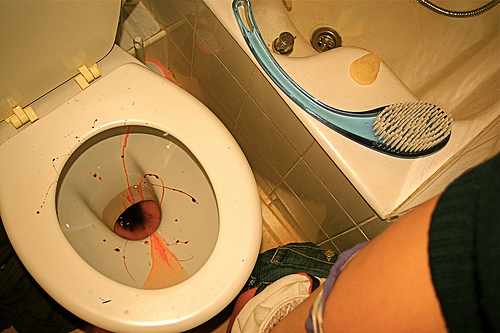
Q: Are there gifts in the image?
A: No, there are no gifts.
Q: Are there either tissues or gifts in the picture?
A: No, there are no gifts or tissues.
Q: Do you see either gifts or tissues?
A: No, there are no gifts or tissues.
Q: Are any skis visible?
A: No, there are no skis.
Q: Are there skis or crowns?
A: No, there are no skis or crowns.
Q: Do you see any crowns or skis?
A: No, there are no skis or crowns.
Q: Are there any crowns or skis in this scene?
A: No, there are no skis or crowns.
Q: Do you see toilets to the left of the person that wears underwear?
A: Yes, there is a toilet to the left of the person.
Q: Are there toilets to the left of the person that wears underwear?
A: Yes, there is a toilet to the left of the person.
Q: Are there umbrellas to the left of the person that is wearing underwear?
A: No, there is a toilet to the left of the person.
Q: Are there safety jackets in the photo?
A: No, there are no safety jackets.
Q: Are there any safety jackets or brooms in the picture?
A: No, there are no safety jackets or brooms.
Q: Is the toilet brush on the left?
A: Yes, the toilet brush is on the left of the image.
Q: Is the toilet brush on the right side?
A: No, the toilet brush is on the left of the image.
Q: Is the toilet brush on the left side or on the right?
A: The toilet brush is on the left of the image.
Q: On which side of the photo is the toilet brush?
A: The toilet brush is on the left of the image.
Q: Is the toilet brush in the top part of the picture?
A: Yes, the toilet brush is in the top of the image.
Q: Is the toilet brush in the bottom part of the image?
A: No, the toilet brush is in the top of the image.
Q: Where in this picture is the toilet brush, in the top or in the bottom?
A: The toilet brush is in the top of the image.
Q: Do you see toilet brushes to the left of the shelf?
A: Yes, there is a toilet brush to the left of the shelf.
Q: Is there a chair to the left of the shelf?
A: No, there is a toilet brush to the left of the shelf.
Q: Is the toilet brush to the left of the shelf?
A: Yes, the toilet brush is to the left of the shelf.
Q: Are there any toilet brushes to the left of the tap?
A: Yes, there is a toilet brush to the left of the tap.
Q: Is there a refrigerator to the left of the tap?
A: No, there is a toilet brush to the left of the tap.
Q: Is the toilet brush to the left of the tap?
A: Yes, the toilet brush is to the left of the tap.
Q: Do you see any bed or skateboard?
A: No, there are no skateboards or beds.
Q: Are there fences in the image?
A: No, there are no fences.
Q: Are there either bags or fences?
A: No, there are no fences or bags.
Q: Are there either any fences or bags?
A: No, there are no fences or bags.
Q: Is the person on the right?
A: Yes, the person is on the right of the image.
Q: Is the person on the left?
A: No, the person is on the right of the image.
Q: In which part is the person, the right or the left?
A: The person is on the right of the image.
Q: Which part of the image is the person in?
A: The person is on the right of the image.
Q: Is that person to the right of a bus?
A: No, the person is to the right of a toilet.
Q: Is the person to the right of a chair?
A: No, the person is to the right of a toilet.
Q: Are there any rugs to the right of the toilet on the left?
A: No, there is a person to the right of the toilet.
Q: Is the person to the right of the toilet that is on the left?
A: Yes, the person is to the right of the toilet.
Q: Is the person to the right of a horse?
A: No, the person is to the right of the toilet.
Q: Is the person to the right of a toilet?
A: Yes, the person is to the right of a toilet.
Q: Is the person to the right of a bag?
A: No, the person is to the right of a toilet.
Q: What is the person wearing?
A: The person is wearing underwear.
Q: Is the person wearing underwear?
A: Yes, the person is wearing underwear.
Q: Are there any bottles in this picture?
A: No, there are no bottles.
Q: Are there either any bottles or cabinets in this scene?
A: No, there are no bottles or cabinets.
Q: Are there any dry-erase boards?
A: No, there are no dry-erase boards.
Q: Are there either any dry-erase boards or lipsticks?
A: No, there are no dry-erase boards or lipsticks.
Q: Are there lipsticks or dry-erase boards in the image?
A: No, there are no dry-erase boards or lipsticks.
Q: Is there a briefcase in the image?
A: No, there are no briefcases.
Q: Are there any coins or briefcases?
A: No, there are no briefcases or coins.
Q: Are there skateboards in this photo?
A: No, there are no skateboards.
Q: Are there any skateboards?
A: No, there are no skateboards.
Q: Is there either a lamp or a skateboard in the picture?
A: No, there are no skateboards or lamps.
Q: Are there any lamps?
A: No, there are no lamps.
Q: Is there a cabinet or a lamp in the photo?
A: No, there are no lamps or cabinets.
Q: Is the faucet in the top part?
A: Yes, the faucet is in the top of the image.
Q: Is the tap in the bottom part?
A: No, the tap is in the top of the image.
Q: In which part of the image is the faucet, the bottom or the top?
A: The faucet is in the top of the image.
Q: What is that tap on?
A: The tap is on the bath tub.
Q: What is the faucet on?
A: The tap is on the bath tub.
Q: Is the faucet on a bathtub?
A: Yes, the faucet is on a bathtub.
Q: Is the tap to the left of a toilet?
A: No, the tap is to the right of a toilet.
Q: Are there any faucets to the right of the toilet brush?
A: Yes, there is a faucet to the right of the toilet brush.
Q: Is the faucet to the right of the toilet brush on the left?
A: Yes, the faucet is to the right of the toilet brush.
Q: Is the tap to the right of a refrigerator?
A: No, the tap is to the right of the toilet brush.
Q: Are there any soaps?
A: No, there are no soaps.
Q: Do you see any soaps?
A: No, there are no soaps.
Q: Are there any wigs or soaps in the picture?
A: No, there are no soaps or wigs.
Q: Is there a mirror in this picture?
A: No, there are no mirrors.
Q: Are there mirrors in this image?
A: No, there are no mirrors.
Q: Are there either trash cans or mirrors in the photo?
A: No, there are no mirrors or trash cans.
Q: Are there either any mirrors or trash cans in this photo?
A: No, there are no mirrors or trash cans.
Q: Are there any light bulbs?
A: No, there are no light bulbs.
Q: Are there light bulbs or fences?
A: No, there are no light bulbs or fences.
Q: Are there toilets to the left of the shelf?
A: Yes, there is a toilet to the left of the shelf.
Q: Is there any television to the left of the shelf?
A: No, there is a toilet to the left of the shelf.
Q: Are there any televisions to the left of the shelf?
A: No, there is a toilet to the left of the shelf.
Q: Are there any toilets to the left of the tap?
A: Yes, there is a toilet to the left of the tap.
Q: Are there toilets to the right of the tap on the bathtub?
A: No, the toilet is to the left of the faucet.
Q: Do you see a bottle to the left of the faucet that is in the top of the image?
A: No, there is a toilet to the left of the faucet.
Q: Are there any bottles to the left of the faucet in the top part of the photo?
A: No, there is a toilet to the left of the faucet.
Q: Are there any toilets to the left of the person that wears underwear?
A: Yes, there is a toilet to the left of the person.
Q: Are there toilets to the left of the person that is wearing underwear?
A: Yes, there is a toilet to the left of the person.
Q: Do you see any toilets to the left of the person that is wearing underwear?
A: Yes, there is a toilet to the left of the person.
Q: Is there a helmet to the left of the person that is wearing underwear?
A: No, there is a toilet to the left of the person.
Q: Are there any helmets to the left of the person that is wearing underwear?
A: No, there is a toilet to the left of the person.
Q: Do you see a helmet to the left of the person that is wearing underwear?
A: No, there is a toilet to the left of the person.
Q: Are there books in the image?
A: No, there are no books.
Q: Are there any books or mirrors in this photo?
A: No, there are no books or mirrors.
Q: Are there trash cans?
A: No, there are no trash cans.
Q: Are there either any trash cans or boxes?
A: No, there are no trash cans or boxes.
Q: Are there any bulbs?
A: No, there are no bulbs.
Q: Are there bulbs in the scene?
A: No, there are no bulbs.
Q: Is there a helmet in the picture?
A: No, there are no helmets.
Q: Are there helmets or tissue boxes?
A: No, there are no helmets or tissue boxes.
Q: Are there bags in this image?
A: No, there are no bags.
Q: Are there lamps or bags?
A: No, there are no bags or lamps.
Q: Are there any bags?
A: No, there are no bags.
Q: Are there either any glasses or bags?
A: No, there are no bags or glasses.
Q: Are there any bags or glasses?
A: No, there are no bags or glasses.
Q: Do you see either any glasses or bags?
A: No, there are no bags or glasses.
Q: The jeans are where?
A: The jeans are on the floor.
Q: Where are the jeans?
A: The jeans are on the floor.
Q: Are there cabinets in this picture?
A: No, there are no cabinets.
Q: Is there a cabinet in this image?
A: No, there are no cabinets.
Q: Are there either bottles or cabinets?
A: No, there are no cabinets or bottles.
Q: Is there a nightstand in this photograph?
A: No, there are no nightstands.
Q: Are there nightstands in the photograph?
A: No, there are no nightstands.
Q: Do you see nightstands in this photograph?
A: No, there are no nightstands.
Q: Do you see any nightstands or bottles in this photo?
A: No, there are no nightstands or bottles.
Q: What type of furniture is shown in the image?
A: The furniture is a shelf.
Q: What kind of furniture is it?
A: The piece of furniture is a shelf.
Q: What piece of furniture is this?
A: This is a shelf.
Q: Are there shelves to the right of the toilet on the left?
A: Yes, there is a shelf to the right of the toilet.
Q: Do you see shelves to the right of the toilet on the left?
A: Yes, there is a shelf to the right of the toilet.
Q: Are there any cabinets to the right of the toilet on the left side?
A: No, there is a shelf to the right of the toilet.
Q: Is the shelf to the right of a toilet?
A: Yes, the shelf is to the right of a toilet.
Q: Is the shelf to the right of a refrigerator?
A: No, the shelf is to the right of a toilet.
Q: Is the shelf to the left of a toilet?
A: No, the shelf is to the right of a toilet.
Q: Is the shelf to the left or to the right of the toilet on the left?
A: The shelf is to the right of the toilet.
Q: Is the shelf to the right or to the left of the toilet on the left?
A: The shelf is to the right of the toilet.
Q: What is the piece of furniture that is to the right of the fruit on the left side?
A: The piece of furniture is a shelf.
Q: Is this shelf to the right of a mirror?
A: No, the shelf is to the right of a toilet.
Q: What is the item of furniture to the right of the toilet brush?
A: The piece of furniture is a shelf.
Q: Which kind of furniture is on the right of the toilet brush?
A: The piece of furniture is a shelf.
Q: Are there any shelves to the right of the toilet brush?
A: Yes, there is a shelf to the right of the toilet brush.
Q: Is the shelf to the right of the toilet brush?
A: Yes, the shelf is to the right of the toilet brush.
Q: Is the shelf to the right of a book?
A: No, the shelf is to the right of the toilet brush.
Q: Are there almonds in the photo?
A: No, there are no almonds.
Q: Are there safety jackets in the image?
A: No, there are no safety jackets.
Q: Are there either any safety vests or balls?
A: No, there are no safety vests or balls.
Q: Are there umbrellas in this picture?
A: No, there are no umbrellas.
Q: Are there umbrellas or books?
A: No, there are no umbrellas or books.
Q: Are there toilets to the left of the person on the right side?
A: Yes, there is a toilet to the left of the person.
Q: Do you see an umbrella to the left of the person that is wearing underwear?
A: No, there is a toilet to the left of the person.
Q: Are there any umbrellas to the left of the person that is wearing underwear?
A: No, there is a toilet to the left of the person.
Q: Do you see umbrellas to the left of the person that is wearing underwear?
A: No, there is a toilet to the left of the person.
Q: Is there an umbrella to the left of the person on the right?
A: No, there is a toilet to the left of the person.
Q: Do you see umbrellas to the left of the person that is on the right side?
A: No, there is a toilet to the left of the person.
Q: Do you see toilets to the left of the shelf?
A: Yes, there is a toilet to the left of the shelf.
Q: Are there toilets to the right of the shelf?
A: No, the toilet is to the left of the shelf.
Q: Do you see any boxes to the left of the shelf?
A: No, there is a toilet to the left of the shelf.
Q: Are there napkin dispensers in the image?
A: No, there are no napkin dispensers.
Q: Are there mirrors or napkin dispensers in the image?
A: No, there are no napkin dispensers or mirrors.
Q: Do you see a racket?
A: No, there are no rackets.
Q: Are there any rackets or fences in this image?
A: No, there are no rackets or fences.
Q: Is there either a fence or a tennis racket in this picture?
A: No, there are no rackets or fences.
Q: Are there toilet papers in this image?
A: No, there are no toilet papers.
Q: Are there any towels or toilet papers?
A: No, there are no toilet papers or towels.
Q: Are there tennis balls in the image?
A: No, there are no tennis balls.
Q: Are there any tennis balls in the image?
A: No, there are no tennis balls.